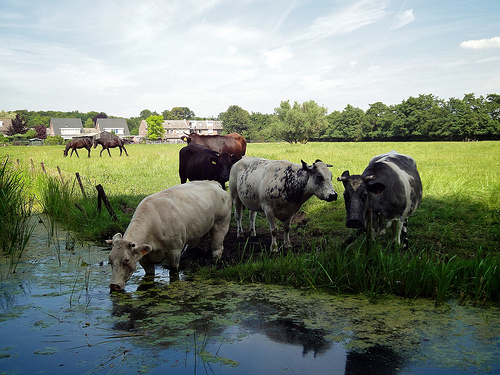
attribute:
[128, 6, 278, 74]
clouds — white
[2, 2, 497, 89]
sky — blue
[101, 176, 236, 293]
cow — tan, black, white, here, drinking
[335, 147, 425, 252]
cow — black, white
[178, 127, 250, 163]
cow — brown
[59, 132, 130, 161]
two horses — grazing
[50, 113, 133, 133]
roofs — black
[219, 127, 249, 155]
cow — brown